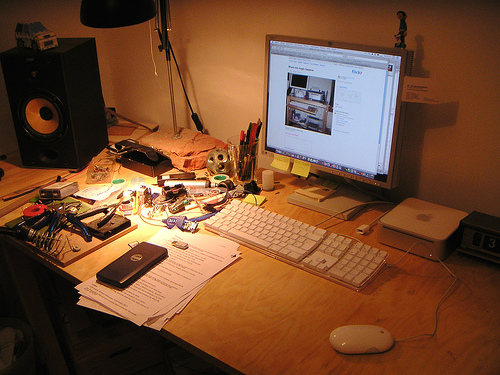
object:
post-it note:
[291, 159, 311, 178]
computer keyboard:
[203, 198, 390, 291]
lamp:
[79, 1, 181, 139]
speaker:
[0, 37, 109, 168]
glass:
[226, 133, 262, 184]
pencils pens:
[238, 118, 261, 181]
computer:
[261, 34, 410, 221]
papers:
[74, 235, 241, 327]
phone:
[96, 241, 168, 288]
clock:
[455, 210, 499, 263]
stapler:
[105, 138, 172, 177]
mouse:
[329, 324, 394, 354]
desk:
[0, 155, 498, 375]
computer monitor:
[261, 34, 409, 190]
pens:
[226, 119, 262, 188]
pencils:
[255, 118, 261, 142]